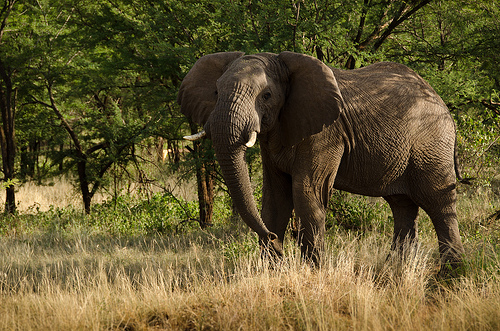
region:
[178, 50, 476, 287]
a large grey elephant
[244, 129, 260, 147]
a short elephant tusk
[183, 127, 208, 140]
a short elephant tusk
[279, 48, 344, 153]
an elephant's left ear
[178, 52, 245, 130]
an elephant's right ear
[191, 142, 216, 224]
a brown tree trunk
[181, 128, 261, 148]
White tusks on elephant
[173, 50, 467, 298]
Adult elephant in forest clearing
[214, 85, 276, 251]
Trunk on elephant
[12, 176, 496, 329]
Tall dry grass on ground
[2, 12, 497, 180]
Leaf covered trees in background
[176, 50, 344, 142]
Large ears on elephant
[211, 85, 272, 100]
Eyes on adult elephant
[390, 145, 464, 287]
Rear legs on elephant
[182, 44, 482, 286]
Elephant walking in the grass.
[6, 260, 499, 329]
Tall brown and green grass.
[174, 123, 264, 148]
Pair of white elephant tusks.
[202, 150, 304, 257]
elephant trunk hanging low to the floor.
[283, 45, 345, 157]
A large elephant ear.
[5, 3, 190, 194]
Row of tall trees.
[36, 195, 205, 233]
Set of green bushes.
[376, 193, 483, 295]
An elephants back legs.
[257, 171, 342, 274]
An elephants front legs.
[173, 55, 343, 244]
Head of a large elephant.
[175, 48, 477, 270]
an elephant in the grass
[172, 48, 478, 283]
an elephant near a tree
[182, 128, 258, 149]
a pair of elephant tusks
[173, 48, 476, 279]
a huge elephant outside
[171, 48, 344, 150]
a large pair of elephant ears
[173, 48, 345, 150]
big wrinkled elephant ears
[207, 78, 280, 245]
a long elephant trunk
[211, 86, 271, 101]
a pair of elephant eyes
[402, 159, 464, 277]
a thick elephant leg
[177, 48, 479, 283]
an elephant in the wild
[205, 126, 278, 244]
Long grey elephant trunk.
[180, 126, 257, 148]
White elephant tusks.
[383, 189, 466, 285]
Two back grey elephant legs.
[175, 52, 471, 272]
A brown elephant.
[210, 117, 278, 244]
A long brown elephant trunk.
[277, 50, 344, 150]
A left brown elephant ear.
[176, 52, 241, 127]
A right brown elephant ear.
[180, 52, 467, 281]
A very big elephant.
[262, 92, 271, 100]
An elephants left eye.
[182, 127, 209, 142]
An elephants right tusk.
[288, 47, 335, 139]
large ear on elephant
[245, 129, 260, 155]
one of the elephant's tusks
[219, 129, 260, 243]
trunk on the elephant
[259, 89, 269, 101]
one of the eyes on elephant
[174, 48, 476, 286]
elephant has black eye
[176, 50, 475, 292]
elephant has large ears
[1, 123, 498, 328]
grass is tall and brown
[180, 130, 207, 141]
ivory tusk is pointed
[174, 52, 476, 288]
elephant has a thin tail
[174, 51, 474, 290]
elephant has a long trunk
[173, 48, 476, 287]
elephant is brownish gray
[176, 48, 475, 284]
elephant has thick legs